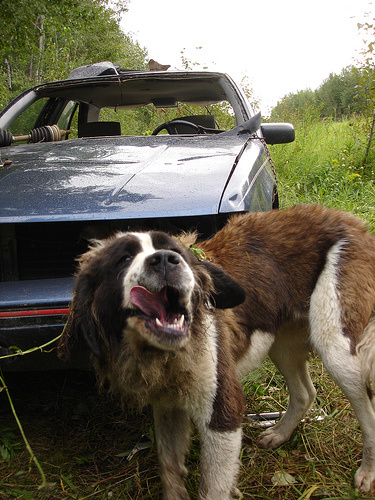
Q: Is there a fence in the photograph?
A: No, there are no fences.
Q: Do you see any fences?
A: No, there are no fences.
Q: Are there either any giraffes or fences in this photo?
A: No, there are no fences or giraffes.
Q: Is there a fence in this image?
A: No, there are no fences.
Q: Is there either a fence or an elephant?
A: No, there are no fences or elephants.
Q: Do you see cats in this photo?
A: No, there are no cats.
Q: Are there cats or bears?
A: No, there are no cats or bears.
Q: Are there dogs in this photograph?
A: Yes, there is a dog.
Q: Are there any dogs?
A: Yes, there is a dog.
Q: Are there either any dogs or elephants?
A: Yes, there is a dog.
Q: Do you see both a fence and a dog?
A: No, there is a dog but no fences.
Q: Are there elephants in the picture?
A: No, there are no elephants.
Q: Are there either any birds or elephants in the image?
A: No, there are no elephants or birds.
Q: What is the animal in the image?
A: The animal is a dog.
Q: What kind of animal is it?
A: The animal is a dog.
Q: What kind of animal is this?
A: This is a dog.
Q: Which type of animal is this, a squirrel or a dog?
A: This is a dog.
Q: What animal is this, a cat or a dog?
A: This is a dog.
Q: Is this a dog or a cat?
A: This is a dog.